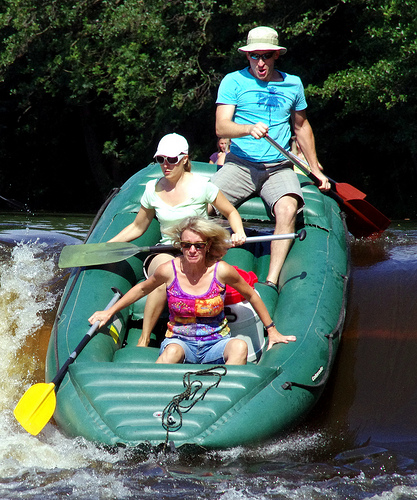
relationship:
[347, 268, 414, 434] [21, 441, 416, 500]
waterfall in a river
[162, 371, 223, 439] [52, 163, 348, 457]
rope on raft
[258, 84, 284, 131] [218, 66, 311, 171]
palm tree on shirt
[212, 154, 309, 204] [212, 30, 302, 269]
shorts on a man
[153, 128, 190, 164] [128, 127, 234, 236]
baseball cap on a woman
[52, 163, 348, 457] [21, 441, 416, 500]
raft in a river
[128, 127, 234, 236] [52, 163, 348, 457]
woman in a raft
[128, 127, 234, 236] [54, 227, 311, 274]
woman holding oar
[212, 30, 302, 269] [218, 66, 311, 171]
man wearing shirt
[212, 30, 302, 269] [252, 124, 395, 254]
man holding oars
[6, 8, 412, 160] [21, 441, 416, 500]
trees near river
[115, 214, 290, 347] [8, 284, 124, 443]
woman holding oar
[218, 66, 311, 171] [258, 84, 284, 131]
shirt has a palm tree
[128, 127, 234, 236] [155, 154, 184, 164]
woman wearing sunglasses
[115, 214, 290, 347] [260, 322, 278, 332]
woman wearing a wrist watch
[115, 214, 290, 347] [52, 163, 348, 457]
woman holding onto raft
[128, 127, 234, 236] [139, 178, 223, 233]
woman wearing a shirt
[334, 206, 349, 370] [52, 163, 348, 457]
rope on side of raft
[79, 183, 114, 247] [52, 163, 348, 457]
rope on side of raft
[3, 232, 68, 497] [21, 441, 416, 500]
rapids in river